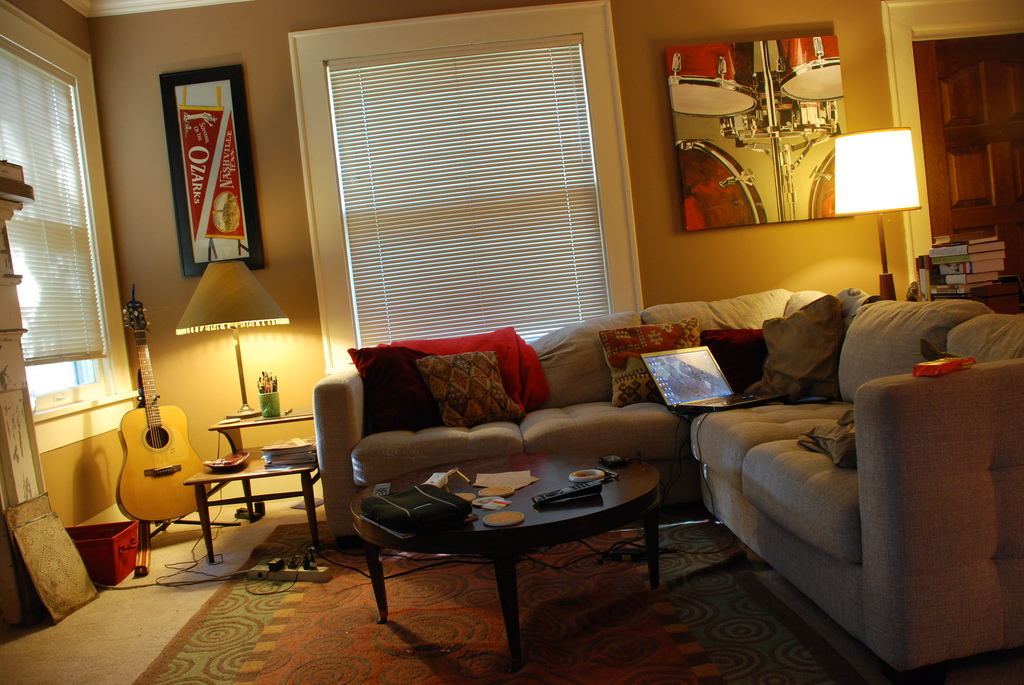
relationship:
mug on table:
[200, 359, 319, 424] [215, 404, 388, 571]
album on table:
[354, 465, 491, 526] [360, 448, 682, 598]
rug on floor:
[135, 513, 924, 680] [14, 450, 1019, 677]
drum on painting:
[669, 66, 775, 133] [660, 18, 847, 234]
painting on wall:
[660, 18, 847, 234] [82, 16, 923, 474]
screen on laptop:
[639, 344, 735, 412] [646, 327, 791, 418]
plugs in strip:
[256, 552, 300, 578] [228, 547, 337, 584]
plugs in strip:
[283, 552, 297, 572] [228, 547, 337, 584]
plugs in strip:
[295, 547, 334, 573] [228, 547, 337, 584]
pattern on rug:
[256, 539, 714, 680] [133, 497, 879, 681]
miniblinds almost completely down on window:
[0, 43, 105, 373] [4, 61, 125, 424]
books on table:
[920, 221, 1009, 295] [870, 277, 1013, 317]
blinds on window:
[328, 40, 609, 349] [283, 5, 668, 416]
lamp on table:
[170, 240, 298, 346] [205, 394, 326, 444]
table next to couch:
[192, 385, 339, 573] [317, 268, 869, 558]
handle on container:
[110, 530, 141, 557] [61, 519, 146, 589]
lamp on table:
[171, 258, 288, 419] [215, 405, 330, 527]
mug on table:
[256, 390, 282, 422] [209, 405, 328, 520]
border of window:
[287, 33, 361, 384] [321, 31, 618, 354]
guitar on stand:
[105, 294, 216, 521] [114, 279, 249, 584]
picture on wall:
[146, 57, 276, 282] [96, 9, 380, 470]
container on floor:
[62, 515, 151, 589] [0, 469, 886, 679]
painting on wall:
[660, 26, 859, 245] [617, 9, 909, 312]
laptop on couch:
[632, 342, 792, 412] [310, 284, 993, 678]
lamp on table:
[171, 258, 288, 419] [204, 404, 347, 532]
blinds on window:
[328, 40, 609, 349] [287, 7, 644, 390]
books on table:
[924, 229, 992, 286] [930, 282, 993, 300]